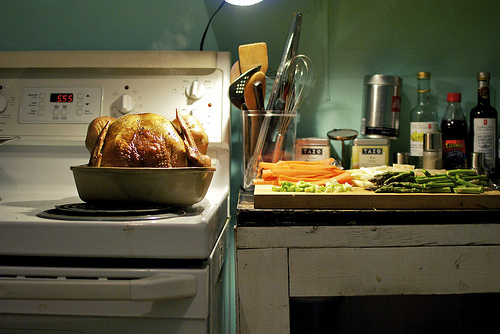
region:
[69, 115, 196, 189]
This is a picture of a turkey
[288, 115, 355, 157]
These are tazo teas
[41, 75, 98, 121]
The time says "5:55"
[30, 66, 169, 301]
This is a stove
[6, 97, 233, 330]
The stove is white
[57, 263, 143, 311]
This is a handle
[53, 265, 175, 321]
This is an oven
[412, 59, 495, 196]
These are oils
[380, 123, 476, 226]
This is asparagus that is green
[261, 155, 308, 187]
These are carrots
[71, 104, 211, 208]
A turkey in the tray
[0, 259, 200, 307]
The handle of oven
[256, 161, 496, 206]
Veggies on the cutting board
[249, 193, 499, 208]
cutting board on the counter top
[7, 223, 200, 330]
The dirty spots on the white oven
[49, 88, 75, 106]
the clock on the oven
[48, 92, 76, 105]
The red lights on the stove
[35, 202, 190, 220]
The grill of the stove top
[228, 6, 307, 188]
A bucket of kitchen utensils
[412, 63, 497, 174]
Bottles on the top of the counter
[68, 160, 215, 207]
A large cooking pan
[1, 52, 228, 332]
A white oven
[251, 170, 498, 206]
A wooden cutting board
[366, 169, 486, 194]
some asparagus on the cutting board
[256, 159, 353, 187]
some carrots on the cutting board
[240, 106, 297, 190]
A glass utensil holder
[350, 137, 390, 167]
A tea tin on the counter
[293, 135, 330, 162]
A tea tin on the counter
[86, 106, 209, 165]
A cooked turkey in the pan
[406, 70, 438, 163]
A glass bottle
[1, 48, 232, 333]
a white stove top oven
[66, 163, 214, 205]
a metal roasting pan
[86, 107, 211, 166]
a brown baked turkey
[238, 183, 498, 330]
a white wooden table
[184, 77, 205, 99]
a stove top dial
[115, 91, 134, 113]
a stove top dial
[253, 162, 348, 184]
slices of carrots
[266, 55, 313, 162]
a metal wire whisk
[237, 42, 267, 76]
a tan spatula head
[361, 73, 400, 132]
a shiny metal canister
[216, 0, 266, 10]
bright white circular light over stove and counter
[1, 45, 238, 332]
white metal stove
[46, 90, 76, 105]
black and red digital clock on stove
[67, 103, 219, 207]
brown and yellow cooked turkey in pan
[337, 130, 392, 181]
square metal tea container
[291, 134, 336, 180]
square metal tea container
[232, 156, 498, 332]
white wooden table with black top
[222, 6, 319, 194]
many kitchen utensils in clear container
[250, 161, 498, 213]
large wooden rectangular flat chopping board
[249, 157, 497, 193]
assorted vegetables on chopping board